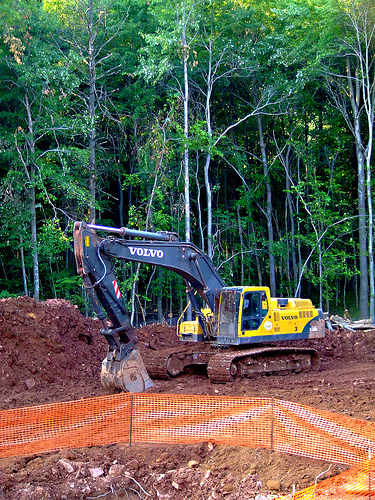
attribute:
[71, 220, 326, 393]
volvo tractor — large, black, yellow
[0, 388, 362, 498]
fence — orange, mesh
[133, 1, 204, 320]
tree — tall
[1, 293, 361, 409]
dirt — loose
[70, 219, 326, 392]
backhoe — yellow, black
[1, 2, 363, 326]
stand — thick